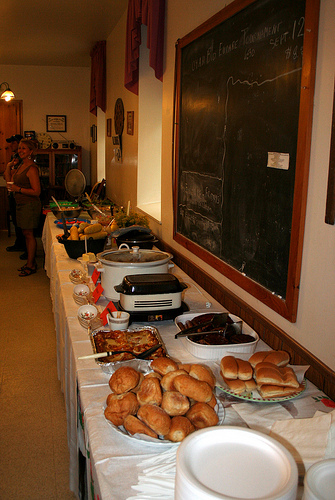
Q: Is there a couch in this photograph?
A: No, there are no couches.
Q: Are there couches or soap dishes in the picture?
A: No, there are no couches or soap dishes.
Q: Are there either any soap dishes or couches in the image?
A: No, there are no couches or soap dishes.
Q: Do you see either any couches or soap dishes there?
A: No, there are no couches or soap dishes.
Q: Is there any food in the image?
A: Yes, there is food.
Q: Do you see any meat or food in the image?
A: Yes, there is food.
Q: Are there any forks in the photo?
A: No, there are no forks.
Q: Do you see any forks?
A: No, there are no forks.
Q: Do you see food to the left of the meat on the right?
A: Yes, there is food to the left of the meat.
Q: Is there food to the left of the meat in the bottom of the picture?
A: Yes, there is food to the left of the meat.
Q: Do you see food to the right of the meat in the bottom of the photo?
A: No, the food is to the left of the meat.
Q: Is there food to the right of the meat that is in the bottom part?
A: No, the food is to the left of the meat.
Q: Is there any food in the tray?
A: Yes, there is food in the tray.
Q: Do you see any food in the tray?
A: Yes, there is food in the tray.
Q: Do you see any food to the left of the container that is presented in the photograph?
A: Yes, there is food to the left of the container.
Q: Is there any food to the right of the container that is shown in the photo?
A: No, the food is to the left of the container.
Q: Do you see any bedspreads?
A: No, there are no bedspreads.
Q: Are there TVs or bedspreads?
A: No, there are no bedspreads or tvs.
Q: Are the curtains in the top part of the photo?
A: Yes, the curtains are in the top of the image.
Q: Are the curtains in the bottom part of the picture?
A: No, the curtains are in the top of the image.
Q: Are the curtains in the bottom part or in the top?
A: The curtains are in the top of the image.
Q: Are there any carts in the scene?
A: No, there are no carts.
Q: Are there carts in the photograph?
A: No, there are no carts.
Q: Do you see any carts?
A: No, there are no carts.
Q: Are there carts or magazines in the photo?
A: No, there are no carts or magazines.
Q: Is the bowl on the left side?
A: Yes, the bowl is on the left of the image.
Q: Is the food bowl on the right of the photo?
A: No, the bowl is on the left of the image.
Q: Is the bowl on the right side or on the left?
A: The bowl is on the left of the image.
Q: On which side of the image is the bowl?
A: The bowl is on the left of the image.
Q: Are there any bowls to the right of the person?
A: Yes, there is a bowl to the right of the person.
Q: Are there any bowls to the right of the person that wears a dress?
A: Yes, there is a bowl to the right of the person.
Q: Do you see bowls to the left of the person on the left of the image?
A: No, the bowl is to the right of the person.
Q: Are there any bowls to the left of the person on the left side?
A: No, the bowl is to the right of the person.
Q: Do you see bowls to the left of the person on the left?
A: No, the bowl is to the right of the person.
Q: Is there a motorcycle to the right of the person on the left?
A: No, there is a bowl to the right of the person.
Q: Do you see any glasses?
A: No, there are no glasses.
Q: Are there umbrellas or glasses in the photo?
A: No, there are no glasses or umbrellas.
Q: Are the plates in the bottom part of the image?
A: Yes, the plates are in the bottom of the image.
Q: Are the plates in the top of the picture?
A: No, the plates are in the bottom of the image.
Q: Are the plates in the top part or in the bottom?
A: The plates are in the bottom of the image.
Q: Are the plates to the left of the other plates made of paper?
A: Yes, the plates are made of paper.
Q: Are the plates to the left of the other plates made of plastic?
A: No, the plates are made of paper.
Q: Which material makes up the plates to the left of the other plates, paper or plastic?
A: The plates are made of paper.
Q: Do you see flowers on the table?
A: No, there are plates on the table.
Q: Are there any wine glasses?
A: No, there are no wine glasses.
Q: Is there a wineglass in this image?
A: No, there are no wine glasses.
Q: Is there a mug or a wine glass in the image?
A: No, there are no wine glasses or mugs.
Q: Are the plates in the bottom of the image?
A: Yes, the plates are in the bottom of the image.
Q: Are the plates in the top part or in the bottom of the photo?
A: The plates are in the bottom of the image.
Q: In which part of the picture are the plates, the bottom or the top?
A: The plates are in the bottom of the image.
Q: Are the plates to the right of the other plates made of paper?
A: Yes, the plates are made of paper.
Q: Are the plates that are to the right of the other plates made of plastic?
A: No, the plates are made of paper.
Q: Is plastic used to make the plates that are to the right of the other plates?
A: No, the plates are made of paper.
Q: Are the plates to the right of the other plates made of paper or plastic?
A: The plates are made of paper.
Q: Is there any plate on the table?
A: Yes, there are plates on the table.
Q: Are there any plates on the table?
A: Yes, there are plates on the table.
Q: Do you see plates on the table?
A: Yes, there are plates on the table.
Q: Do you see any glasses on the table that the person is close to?
A: No, there are plates on the table.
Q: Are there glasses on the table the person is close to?
A: No, there are plates on the table.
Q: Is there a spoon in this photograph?
A: Yes, there is a spoon.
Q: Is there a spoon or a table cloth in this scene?
A: Yes, there is a spoon.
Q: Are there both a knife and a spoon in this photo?
A: No, there is a spoon but no knives.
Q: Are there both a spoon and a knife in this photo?
A: No, there is a spoon but no knives.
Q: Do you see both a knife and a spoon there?
A: No, there is a spoon but no knives.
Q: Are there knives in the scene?
A: No, there are no knives.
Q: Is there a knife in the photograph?
A: No, there are no knives.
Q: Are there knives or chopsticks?
A: No, there are no knives or chopsticks.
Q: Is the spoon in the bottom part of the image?
A: Yes, the spoon is in the bottom of the image.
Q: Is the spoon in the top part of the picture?
A: No, the spoon is in the bottom of the image.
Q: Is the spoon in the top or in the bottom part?
A: The spoon is in the bottom of the image.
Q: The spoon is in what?
A: The spoon is in the tray.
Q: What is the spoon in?
A: The spoon is in the tray.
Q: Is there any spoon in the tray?
A: Yes, there is a spoon in the tray.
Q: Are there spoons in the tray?
A: Yes, there is a spoon in the tray.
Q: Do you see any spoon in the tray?
A: Yes, there is a spoon in the tray.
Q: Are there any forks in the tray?
A: No, there is a spoon in the tray.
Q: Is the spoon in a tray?
A: Yes, the spoon is in a tray.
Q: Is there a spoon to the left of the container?
A: Yes, there is a spoon to the left of the container.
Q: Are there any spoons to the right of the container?
A: No, the spoon is to the left of the container.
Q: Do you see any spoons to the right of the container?
A: No, the spoon is to the left of the container.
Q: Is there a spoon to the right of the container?
A: No, the spoon is to the left of the container.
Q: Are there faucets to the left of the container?
A: No, there is a spoon to the left of the container.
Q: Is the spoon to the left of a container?
A: Yes, the spoon is to the left of a container.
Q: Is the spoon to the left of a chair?
A: No, the spoon is to the left of a container.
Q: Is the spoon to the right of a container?
A: No, the spoon is to the left of a container.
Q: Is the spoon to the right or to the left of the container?
A: The spoon is to the left of the container.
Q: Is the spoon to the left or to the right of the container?
A: The spoon is to the left of the container.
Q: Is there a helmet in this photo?
A: No, there are no helmets.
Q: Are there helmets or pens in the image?
A: No, there are no helmets or pens.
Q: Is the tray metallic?
A: Yes, the tray is metallic.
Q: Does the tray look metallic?
A: Yes, the tray is metallic.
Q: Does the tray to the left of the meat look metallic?
A: Yes, the tray is metallic.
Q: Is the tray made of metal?
A: Yes, the tray is made of metal.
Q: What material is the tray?
A: The tray is made of metal.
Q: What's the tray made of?
A: The tray is made of metal.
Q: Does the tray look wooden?
A: No, the tray is metallic.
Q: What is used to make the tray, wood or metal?
A: The tray is made of metal.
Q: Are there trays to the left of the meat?
A: Yes, there is a tray to the left of the meat.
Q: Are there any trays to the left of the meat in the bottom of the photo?
A: Yes, there is a tray to the left of the meat.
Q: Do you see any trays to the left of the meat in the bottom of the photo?
A: Yes, there is a tray to the left of the meat.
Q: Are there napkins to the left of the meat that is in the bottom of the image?
A: No, there is a tray to the left of the meat.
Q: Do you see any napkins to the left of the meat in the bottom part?
A: No, there is a tray to the left of the meat.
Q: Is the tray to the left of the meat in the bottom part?
A: Yes, the tray is to the left of the meat.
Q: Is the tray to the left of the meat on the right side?
A: Yes, the tray is to the left of the meat.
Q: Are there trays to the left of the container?
A: Yes, there is a tray to the left of the container.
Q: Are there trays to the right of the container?
A: No, the tray is to the left of the container.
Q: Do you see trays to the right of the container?
A: No, the tray is to the left of the container.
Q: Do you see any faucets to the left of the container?
A: No, there is a tray to the left of the container.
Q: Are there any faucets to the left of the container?
A: No, there is a tray to the left of the container.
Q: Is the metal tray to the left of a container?
A: Yes, the tray is to the left of a container.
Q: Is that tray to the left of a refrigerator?
A: No, the tray is to the left of a container.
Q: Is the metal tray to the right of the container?
A: No, the tray is to the left of the container.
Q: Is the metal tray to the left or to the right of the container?
A: The tray is to the left of the container.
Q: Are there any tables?
A: Yes, there is a table.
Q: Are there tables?
A: Yes, there is a table.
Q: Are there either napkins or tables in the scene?
A: Yes, there is a table.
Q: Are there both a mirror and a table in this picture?
A: No, there is a table but no mirrors.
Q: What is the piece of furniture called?
A: The piece of furniture is a table.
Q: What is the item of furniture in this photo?
A: The piece of furniture is a table.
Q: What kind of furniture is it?
A: The piece of furniture is a table.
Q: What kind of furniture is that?
A: This is a table.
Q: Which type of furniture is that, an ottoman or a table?
A: This is a table.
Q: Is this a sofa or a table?
A: This is a table.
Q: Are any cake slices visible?
A: No, there are no cake slices.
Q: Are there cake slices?
A: No, there are no cake slices.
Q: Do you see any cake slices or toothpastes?
A: No, there are no cake slices or toothpastes.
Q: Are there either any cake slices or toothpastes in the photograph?
A: No, there are no cake slices or toothpastes.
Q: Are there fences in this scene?
A: No, there are no fences.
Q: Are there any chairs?
A: No, there are no chairs.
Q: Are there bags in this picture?
A: No, there are no bags.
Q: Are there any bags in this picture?
A: No, there are no bags.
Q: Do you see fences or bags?
A: No, there are no bags or fences.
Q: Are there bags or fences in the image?
A: No, there are no bags or fences.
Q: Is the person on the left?
A: Yes, the person is on the left of the image.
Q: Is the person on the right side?
A: No, the person is on the left of the image.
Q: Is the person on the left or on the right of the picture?
A: The person is on the left of the image.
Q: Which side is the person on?
A: The person is on the left of the image.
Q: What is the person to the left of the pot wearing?
A: The person is wearing a dress.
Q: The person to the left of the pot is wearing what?
A: The person is wearing a dress.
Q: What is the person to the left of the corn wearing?
A: The person is wearing a dress.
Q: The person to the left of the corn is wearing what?
A: The person is wearing a dress.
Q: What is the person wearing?
A: The person is wearing a dress.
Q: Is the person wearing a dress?
A: Yes, the person is wearing a dress.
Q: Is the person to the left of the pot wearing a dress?
A: Yes, the person is wearing a dress.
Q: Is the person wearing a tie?
A: No, the person is wearing a dress.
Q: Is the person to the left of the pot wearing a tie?
A: No, the person is wearing a dress.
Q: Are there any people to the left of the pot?
A: Yes, there is a person to the left of the pot.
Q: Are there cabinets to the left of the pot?
A: No, there is a person to the left of the pot.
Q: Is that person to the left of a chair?
A: No, the person is to the left of the pot.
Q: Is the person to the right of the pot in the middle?
A: No, the person is to the left of the pot.